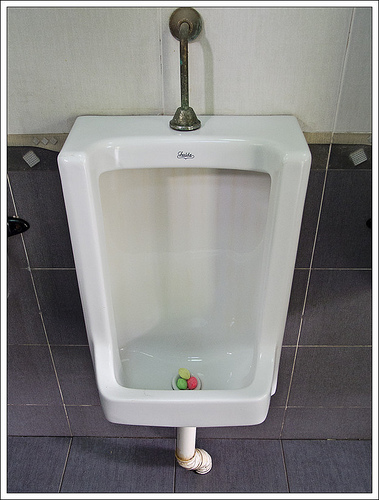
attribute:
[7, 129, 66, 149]
trim — beige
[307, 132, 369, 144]
trim — beige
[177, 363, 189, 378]
urinal cake — yellow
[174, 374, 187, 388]
cake — green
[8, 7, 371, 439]
wall — white, purple and white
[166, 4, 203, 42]
circle — metal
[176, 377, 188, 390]
shape — green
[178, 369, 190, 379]
urinal cakes — round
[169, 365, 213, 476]
drain — white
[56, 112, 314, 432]
white urinal — long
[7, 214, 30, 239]
object — black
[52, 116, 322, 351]
toilet — white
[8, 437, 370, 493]
floor — grey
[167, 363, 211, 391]
urinal cake — pink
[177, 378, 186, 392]
urinal cake — pink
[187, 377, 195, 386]
urinal cake — yellow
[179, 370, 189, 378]
urinal cake — green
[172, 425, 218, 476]
pipe — white